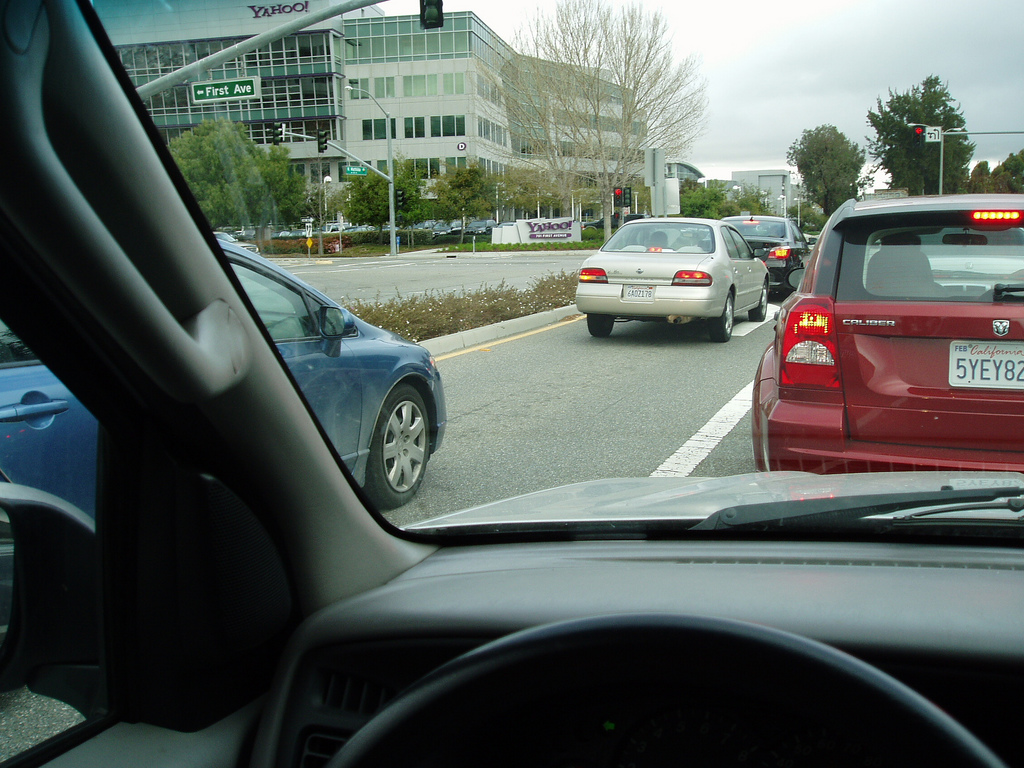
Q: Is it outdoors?
A: Yes, it is outdoors.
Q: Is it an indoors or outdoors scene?
A: It is outdoors.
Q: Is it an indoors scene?
A: No, it is outdoors.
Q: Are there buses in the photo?
A: No, there are no buses.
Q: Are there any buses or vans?
A: No, there are no buses or vans.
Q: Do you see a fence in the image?
A: No, there are no fences.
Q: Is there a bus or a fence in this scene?
A: No, there are no fences or buses.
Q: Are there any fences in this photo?
A: No, there are no fences.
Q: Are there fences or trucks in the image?
A: No, there are no fences or trucks.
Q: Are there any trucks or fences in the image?
A: No, there are no fences or trucks.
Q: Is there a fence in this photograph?
A: No, there are no fences.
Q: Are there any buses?
A: No, there are no buses.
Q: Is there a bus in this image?
A: No, there are no buses.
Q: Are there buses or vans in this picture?
A: No, there are no buses or vans.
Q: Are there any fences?
A: No, there are no fences.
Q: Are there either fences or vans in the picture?
A: No, there are no fences or vans.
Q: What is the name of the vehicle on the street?
A: The vehicle is a car.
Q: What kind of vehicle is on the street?
A: The vehicle is a car.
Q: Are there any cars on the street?
A: Yes, there is a car on the street.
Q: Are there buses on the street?
A: No, there is a car on the street.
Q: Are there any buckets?
A: No, there are no buckets.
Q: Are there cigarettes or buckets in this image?
A: No, there are no buckets or cigarettes.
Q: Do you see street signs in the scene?
A: Yes, there is a street sign.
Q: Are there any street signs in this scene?
A: Yes, there is a street sign.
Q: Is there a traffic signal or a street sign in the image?
A: Yes, there is a street sign.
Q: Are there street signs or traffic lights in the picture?
A: Yes, there is a street sign.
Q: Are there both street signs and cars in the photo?
A: Yes, there are both a street sign and a car.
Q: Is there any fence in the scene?
A: No, there are no fences.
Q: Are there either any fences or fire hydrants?
A: No, there are no fences or fire hydrants.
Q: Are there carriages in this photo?
A: No, there are no carriages.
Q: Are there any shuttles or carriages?
A: No, there are no carriages or shuttles.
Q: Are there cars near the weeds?
A: Yes, there is a car near the weeds.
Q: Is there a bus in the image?
A: No, there are no buses.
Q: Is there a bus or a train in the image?
A: No, there are no buses or trains.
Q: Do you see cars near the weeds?
A: Yes, there is a car near the weeds.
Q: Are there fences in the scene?
A: No, there are no fences.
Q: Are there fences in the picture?
A: No, there are no fences.